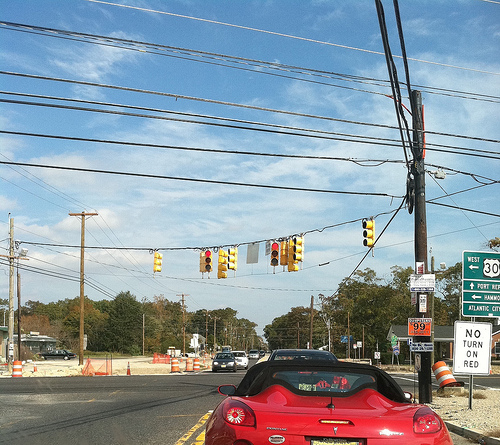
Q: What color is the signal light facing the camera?
A: Red.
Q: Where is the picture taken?
A: The street.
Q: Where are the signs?
A: On the right.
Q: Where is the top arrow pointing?
A: West.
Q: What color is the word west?
A: White.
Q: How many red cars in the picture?
A: 1.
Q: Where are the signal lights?
A: On the wire.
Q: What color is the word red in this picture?
A: Black.